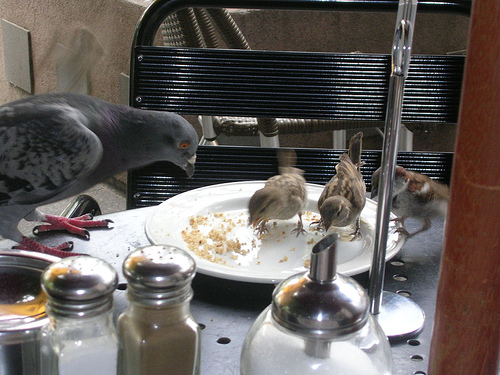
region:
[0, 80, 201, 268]
pigeon looking for food on plate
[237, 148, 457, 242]
three sparrows on an empty plate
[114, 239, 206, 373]
pepper shaker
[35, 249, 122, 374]
salt shaker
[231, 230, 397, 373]
sugar shaker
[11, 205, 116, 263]
pigeon has pink feet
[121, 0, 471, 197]
black metal chair at table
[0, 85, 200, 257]
pigeon is big and gray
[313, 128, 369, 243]
sparrow is light brown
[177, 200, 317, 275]
brown crumbs on empty plate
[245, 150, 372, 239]
two birds standing in a plate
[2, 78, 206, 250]
gray bird sitting on table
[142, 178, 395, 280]
white plate on the table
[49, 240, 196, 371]
salt and pepper shakers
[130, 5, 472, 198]
black chair at the table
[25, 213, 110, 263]
red toes and talons of bird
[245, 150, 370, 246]
two brown birds eating from plate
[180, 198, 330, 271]
crumbs on white plate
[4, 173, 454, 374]
table white plate is on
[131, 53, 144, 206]
bolts on the black chair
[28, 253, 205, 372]
salt and pepper shakers with silver lids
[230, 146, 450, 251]
three birds standing on a white plate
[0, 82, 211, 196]
a grey pigeon standing on a table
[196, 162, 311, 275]
a bird eating crumbs from a plate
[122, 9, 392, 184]
a black metal chair next to a table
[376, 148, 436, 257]
a bird standing on the edge of a plate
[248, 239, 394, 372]
a container of sugar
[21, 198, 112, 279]
a bird with pink feet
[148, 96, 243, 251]
a bird looking at a white plate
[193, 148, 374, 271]
birds eating crumbs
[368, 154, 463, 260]
This is a bird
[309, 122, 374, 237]
This is a bird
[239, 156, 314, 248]
This is a bird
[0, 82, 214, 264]
This is a bird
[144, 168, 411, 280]
This is a plate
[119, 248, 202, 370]
This is a bottle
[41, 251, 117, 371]
This is a bottle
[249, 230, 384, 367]
This is a bottle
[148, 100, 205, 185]
Head of a bird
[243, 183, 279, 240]
Head of a bird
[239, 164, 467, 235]
The birds are brown.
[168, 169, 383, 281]
The plate is white.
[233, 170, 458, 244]
The birds are small.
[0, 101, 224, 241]
The pigeon is on the table.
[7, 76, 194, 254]
The pigeon is gray.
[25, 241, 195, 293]
The lids are silver.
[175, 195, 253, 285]
The crumbs are on the table.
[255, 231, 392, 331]
The lid is silver.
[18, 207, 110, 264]
His feet are orange.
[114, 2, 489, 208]
The chair is black.